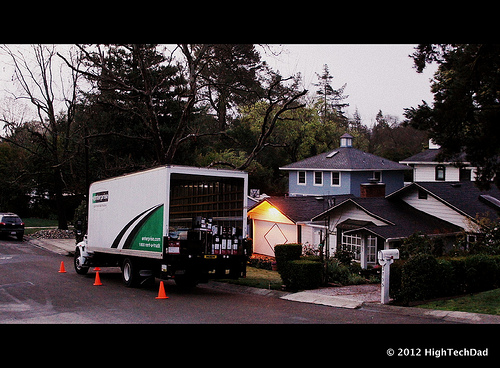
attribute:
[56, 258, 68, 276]
cone — orange, upright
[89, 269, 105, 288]
cone — orange, upright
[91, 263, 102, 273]
cone — orange, upright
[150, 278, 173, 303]
cone — orange, upright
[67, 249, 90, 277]
tire — round, black, inflated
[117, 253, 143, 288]
tire — round, black, inflated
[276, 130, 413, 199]
house — blue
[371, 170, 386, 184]
window — closed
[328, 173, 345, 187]
window — closed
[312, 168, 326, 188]
window — closed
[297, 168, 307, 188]
window — closed